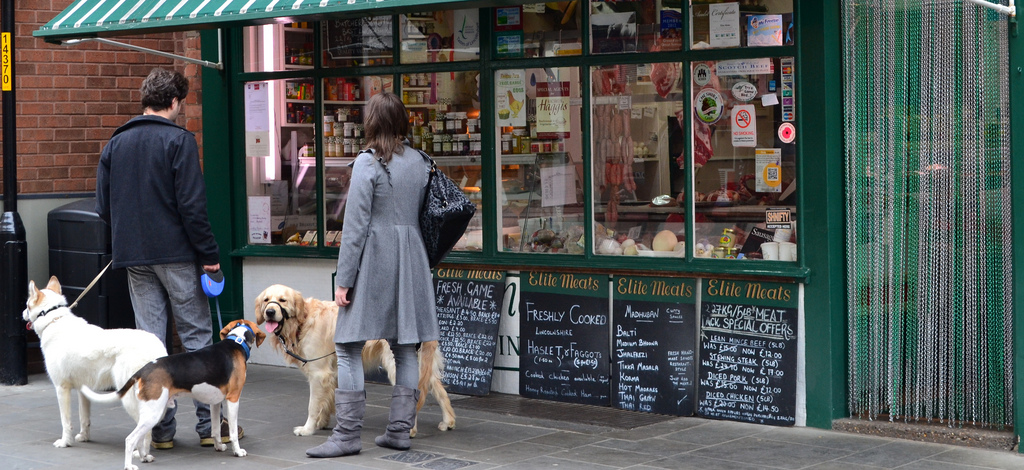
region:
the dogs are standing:
[21, 274, 455, 465]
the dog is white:
[21, 272, 168, 457]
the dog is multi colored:
[80, 319, 265, 468]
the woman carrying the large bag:
[307, 88, 476, 458]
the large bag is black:
[412, 141, 477, 274]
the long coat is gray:
[334, 142, 442, 349]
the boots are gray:
[307, 388, 421, 459]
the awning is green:
[32, 0, 447, 39]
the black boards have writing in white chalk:
[425, 281, 798, 433]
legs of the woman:
[296, 268, 471, 466]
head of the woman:
[332, 60, 450, 179]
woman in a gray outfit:
[272, 67, 504, 390]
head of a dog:
[237, 265, 317, 365]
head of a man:
[107, 48, 218, 150]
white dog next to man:
[3, 209, 193, 413]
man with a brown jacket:
[75, 45, 250, 286]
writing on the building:
[470, 249, 812, 423]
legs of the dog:
[100, 376, 262, 460]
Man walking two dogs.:
[22, 49, 258, 457]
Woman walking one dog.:
[257, 91, 476, 445]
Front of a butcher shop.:
[212, 0, 801, 408]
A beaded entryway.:
[837, 0, 1021, 443]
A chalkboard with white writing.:
[690, 303, 798, 422]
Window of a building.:
[687, 56, 798, 260]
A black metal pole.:
[0, 5, 24, 388]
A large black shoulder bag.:
[414, 148, 473, 266]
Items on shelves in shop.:
[284, 27, 478, 157]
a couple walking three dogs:
[12, 61, 481, 460]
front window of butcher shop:
[233, 7, 804, 261]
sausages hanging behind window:
[581, 48, 699, 263]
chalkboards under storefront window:
[242, 23, 808, 428]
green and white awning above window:
[40, 0, 487, 257]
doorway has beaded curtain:
[796, 5, 1021, 448]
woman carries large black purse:
[321, 90, 478, 452]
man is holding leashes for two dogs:
[17, 64, 262, 467]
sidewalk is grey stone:
[2, 355, 1021, 466]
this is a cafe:
[242, 45, 856, 369]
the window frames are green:
[482, 72, 751, 323]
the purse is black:
[406, 201, 487, 253]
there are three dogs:
[55, 239, 382, 423]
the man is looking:
[70, 45, 251, 276]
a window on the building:
[610, 57, 652, 210]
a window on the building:
[504, 63, 581, 225]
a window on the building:
[399, 83, 466, 254]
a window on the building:
[316, 86, 386, 219]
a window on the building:
[231, 85, 317, 213]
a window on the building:
[668, 12, 779, 58]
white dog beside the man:
[28, 270, 174, 436]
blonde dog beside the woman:
[259, 281, 469, 437]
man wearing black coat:
[97, 58, 243, 338]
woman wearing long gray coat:
[306, 89, 440, 448]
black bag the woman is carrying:
[416, 168, 478, 255]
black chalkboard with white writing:
[322, 264, 795, 417]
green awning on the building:
[37, 6, 393, 51]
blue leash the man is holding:
[196, 263, 229, 327]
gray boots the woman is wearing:
[299, 386, 423, 451]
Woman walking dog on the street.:
[250, 91, 453, 450]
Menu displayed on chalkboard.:
[429, 266, 802, 422]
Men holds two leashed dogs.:
[24, 63, 268, 463]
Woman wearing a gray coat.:
[256, 91, 469, 452]